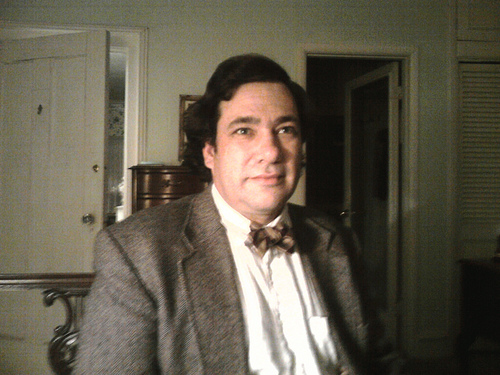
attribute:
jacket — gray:
[83, 199, 404, 373]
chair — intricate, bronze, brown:
[5, 267, 100, 354]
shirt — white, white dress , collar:
[203, 178, 345, 372]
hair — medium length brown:
[190, 49, 317, 181]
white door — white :
[3, 27, 110, 372]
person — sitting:
[72, 49, 388, 373]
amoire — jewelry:
[124, 158, 206, 219]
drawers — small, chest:
[114, 156, 196, 216]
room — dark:
[307, 57, 396, 328]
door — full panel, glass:
[333, 60, 399, 357]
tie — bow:
[244, 219, 302, 260]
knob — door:
[76, 205, 105, 233]